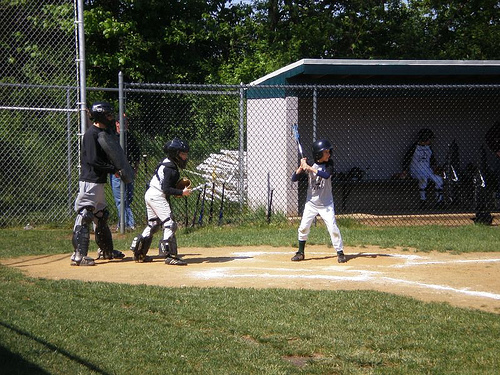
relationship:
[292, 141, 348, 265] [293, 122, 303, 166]
boy holds bat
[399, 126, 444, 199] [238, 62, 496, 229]
player in dugout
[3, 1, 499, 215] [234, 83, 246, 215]
fence has posts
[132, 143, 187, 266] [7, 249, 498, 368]
boy on field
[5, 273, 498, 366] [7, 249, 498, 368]
grass on field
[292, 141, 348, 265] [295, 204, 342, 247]
boy wears pants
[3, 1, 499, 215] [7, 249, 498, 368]
fence behind field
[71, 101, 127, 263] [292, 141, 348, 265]
umpire behind boy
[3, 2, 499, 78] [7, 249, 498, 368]
trees behind field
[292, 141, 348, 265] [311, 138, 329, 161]
boy wears helmet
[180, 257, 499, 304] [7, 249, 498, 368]
lines on field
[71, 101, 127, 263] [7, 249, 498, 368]
umpire on field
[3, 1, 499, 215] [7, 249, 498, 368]
fence around field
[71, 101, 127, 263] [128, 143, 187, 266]
umpire behind boy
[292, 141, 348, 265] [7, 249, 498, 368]
boy on field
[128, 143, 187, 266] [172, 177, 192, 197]
boy holds mitt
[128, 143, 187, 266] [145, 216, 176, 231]
boy wears knee pads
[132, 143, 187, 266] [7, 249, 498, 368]
boy standing on field